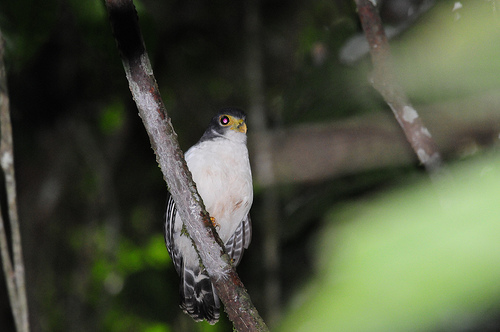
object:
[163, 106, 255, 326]
bird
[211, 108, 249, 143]
head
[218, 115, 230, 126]
eye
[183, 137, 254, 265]
body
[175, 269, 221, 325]
tail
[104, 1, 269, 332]
branch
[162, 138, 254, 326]
feathers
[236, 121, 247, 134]
peck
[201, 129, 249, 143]
neck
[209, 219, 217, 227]
claws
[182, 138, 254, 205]
breast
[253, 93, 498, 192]
branch